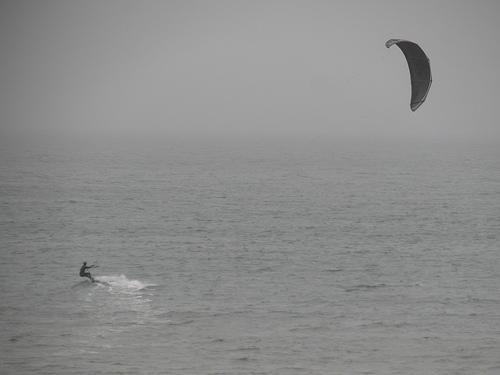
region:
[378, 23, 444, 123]
this is a kite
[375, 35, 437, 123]
the kite is on air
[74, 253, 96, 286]
this is a man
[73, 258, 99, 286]
the man is sea surfing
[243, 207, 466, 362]
this is the sea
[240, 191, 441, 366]
the sea is calm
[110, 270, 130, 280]
the water is splashy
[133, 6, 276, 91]
this is the sky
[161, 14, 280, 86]
the sky is grey in color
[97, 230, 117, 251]
this is a rope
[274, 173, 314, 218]
pat of a water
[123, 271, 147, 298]
part of a splash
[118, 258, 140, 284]
part of a splasj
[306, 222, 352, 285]
part of a water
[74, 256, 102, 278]
part of a person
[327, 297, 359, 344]
part of a water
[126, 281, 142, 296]
part of a splasj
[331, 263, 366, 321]
part of a water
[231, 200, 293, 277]
part of a water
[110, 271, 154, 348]
part of a splash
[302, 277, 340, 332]
part of a water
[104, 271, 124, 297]
part of a splash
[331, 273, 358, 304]
part of a water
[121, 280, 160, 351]
part of a splasj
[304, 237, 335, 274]
part of a water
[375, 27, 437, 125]
grey sale in the sky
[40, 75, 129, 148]
grey colored overcast sky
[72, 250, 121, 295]
wind surfer on a board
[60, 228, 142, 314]
person wind surfing in the ocean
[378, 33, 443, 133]
sale for a wind surfer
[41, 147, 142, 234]
calm grey colored ocean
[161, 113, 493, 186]
hazy horizon in the distance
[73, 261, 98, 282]
wind surfer wearing a wet suit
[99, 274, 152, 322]
white foam from the wake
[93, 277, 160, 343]
wake left by a wind surfer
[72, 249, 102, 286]
kite surfer in the water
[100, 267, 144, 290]
path of kite surfer in the water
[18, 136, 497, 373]
ripples in the water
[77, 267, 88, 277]
black wetsuit of kite surfer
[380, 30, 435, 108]
kite flying in the sky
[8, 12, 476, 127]
gray hazy sky above the ocean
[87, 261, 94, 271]
handlebar surfer is holding onto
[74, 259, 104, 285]
surfer leaning back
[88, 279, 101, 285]
board the kite surfer is standing on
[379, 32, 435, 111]
kite against gray sky